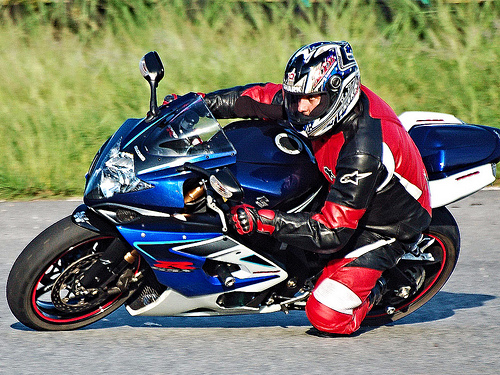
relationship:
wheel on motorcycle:
[3, 194, 153, 337] [14, 35, 499, 374]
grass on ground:
[0, 1, 499, 201] [0, 37, 498, 373]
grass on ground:
[330, 1, 499, 113] [0, 191, 80, 231]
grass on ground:
[0, 1, 499, 201] [3, 0, 498, 373]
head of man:
[277, 33, 397, 145] [241, 22, 445, 354]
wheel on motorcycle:
[350, 200, 467, 316] [26, 92, 498, 309]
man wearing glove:
[163, 40, 430, 333] [231, 198, 276, 233]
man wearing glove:
[163, 40, 430, 333] [161, 87, 201, 128]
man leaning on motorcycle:
[163, 40, 430, 333] [6, 51, 498, 332]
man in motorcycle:
[163, 40, 430, 333] [6, 51, 498, 332]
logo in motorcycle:
[144, 243, 219, 283] [62, 83, 499, 273]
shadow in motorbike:
[409, 287, 493, 331] [5, 49, 498, 331]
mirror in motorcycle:
[136, 48, 171, 94] [6, 51, 498, 332]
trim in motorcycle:
[118, 226, 289, 318] [6, 51, 498, 332]